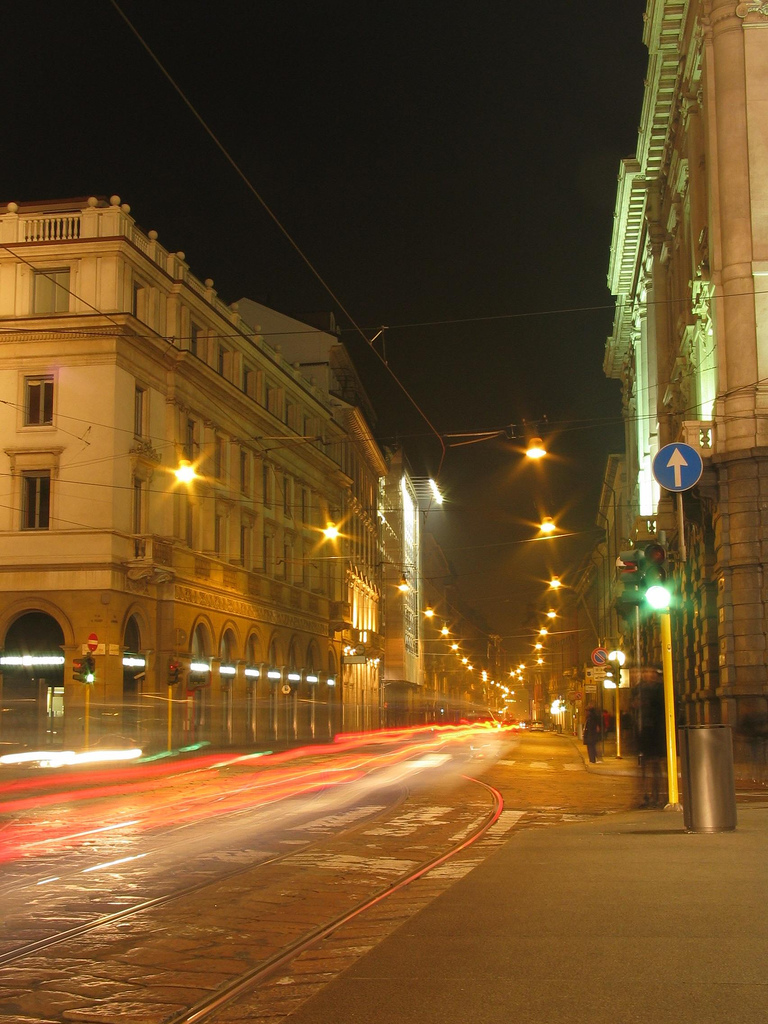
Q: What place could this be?
A: It is a street.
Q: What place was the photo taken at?
A: It was taken at the street.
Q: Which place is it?
A: It is a street.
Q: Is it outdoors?
A: Yes, it is outdoors.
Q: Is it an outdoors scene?
A: Yes, it is outdoors.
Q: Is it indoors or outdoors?
A: It is outdoors.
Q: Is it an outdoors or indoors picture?
A: It is outdoors.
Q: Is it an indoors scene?
A: No, it is outdoors.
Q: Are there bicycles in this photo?
A: No, there are no bicycles.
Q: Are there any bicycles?
A: No, there are no bicycles.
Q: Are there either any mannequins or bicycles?
A: No, there are no bicycles or mannequins.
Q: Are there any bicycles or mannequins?
A: No, there are no bicycles or mannequins.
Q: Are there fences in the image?
A: No, there are no fences.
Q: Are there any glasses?
A: No, there are no glasses.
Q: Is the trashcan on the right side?
A: Yes, the trashcan is on the right of the image.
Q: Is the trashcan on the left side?
A: No, the trashcan is on the right of the image.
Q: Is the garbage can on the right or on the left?
A: The garbage can is on the right of the image.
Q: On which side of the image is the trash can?
A: The trash can is on the right of the image.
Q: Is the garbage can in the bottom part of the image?
A: Yes, the garbage can is in the bottom of the image.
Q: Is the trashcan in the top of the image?
A: No, the trashcan is in the bottom of the image.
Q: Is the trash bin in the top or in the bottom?
A: The trash bin is in the bottom of the image.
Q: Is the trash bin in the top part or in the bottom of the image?
A: The trash bin is in the bottom of the image.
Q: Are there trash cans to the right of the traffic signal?
A: Yes, there is a trash can to the right of the traffic signal.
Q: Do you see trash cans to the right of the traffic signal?
A: Yes, there is a trash can to the right of the traffic signal.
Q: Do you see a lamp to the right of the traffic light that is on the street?
A: No, there is a trash can to the right of the traffic light.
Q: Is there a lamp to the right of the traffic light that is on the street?
A: No, there is a trash can to the right of the traffic light.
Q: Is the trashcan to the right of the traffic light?
A: Yes, the trashcan is to the right of the traffic light.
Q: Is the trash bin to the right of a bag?
A: No, the trash bin is to the right of the traffic light.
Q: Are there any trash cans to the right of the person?
A: Yes, there is a trash can to the right of the person.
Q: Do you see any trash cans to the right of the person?
A: Yes, there is a trash can to the right of the person.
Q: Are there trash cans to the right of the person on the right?
A: Yes, there is a trash can to the right of the person.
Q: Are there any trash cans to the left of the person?
A: No, the trash can is to the right of the person.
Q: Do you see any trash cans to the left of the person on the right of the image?
A: No, the trash can is to the right of the person.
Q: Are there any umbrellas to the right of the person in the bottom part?
A: No, there is a trash can to the right of the person.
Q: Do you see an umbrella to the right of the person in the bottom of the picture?
A: No, there is a trash can to the right of the person.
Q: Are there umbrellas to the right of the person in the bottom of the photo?
A: No, there is a trash can to the right of the person.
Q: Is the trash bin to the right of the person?
A: Yes, the trash bin is to the right of the person.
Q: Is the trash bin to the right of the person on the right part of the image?
A: Yes, the trash bin is to the right of the person.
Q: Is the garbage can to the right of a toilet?
A: No, the garbage can is to the right of the person.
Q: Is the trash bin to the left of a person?
A: No, the trash bin is to the right of a person.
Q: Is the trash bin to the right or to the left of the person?
A: The trash bin is to the right of the person.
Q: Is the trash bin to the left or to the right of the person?
A: The trash bin is to the right of the person.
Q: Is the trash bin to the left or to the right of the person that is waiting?
A: The trash bin is to the right of the person.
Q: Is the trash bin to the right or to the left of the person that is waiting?
A: The trash bin is to the right of the person.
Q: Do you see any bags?
A: No, there are no bags.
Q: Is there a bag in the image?
A: No, there are no bags.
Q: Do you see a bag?
A: No, there are no bags.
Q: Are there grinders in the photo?
A: No, there are no grinders.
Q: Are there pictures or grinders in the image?
A: No, there are no grinders or pictures.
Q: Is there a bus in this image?
A: No, there are no buses.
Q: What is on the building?
A: The sign is on the building.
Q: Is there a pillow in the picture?
A: No, there are no pillows.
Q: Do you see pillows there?
A: No, there are no pillows.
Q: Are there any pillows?
A: No, there are no pillows.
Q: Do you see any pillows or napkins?
A: No, there are no pillows or napkins.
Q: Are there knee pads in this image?
A: No, there are no knee pads.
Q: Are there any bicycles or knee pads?
A: No, there are no knee pads or bicycles.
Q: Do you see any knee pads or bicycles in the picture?
A: No, there are no knee pads or bicycles.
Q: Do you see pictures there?
A: No, there are no pictures.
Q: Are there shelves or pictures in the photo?
A: No, there are no pictures or shelves.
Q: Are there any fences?
A: No, there are no fences.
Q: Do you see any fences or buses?
A: No, there are no fences or buses.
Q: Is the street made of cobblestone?
A: Yes, the street is made of cobblestone.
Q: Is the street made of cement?
A: No, the street is made of cobblestone.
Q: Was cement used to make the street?
A: No, the street is made of cobblestone.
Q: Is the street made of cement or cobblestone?
A: The street is made of cobblestone.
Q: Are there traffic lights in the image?
A: Yes, there is a traffic light.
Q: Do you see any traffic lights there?
A: Yes, there is a traffic light.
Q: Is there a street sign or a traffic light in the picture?
A: Yes, there is a traffic light.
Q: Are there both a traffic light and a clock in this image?
A: No, there is a traffic light but no clocks.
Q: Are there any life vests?
A: No, there are no life vests.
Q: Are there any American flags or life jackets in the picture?
A: No, there are no life jackets or American flags.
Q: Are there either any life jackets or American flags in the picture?
A: No, there are no life jackets or American flags.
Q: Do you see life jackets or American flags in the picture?
A: No, there are no life jackets or American flags.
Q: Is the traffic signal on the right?
A: Yes, the traffic signal is on the right of the image.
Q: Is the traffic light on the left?
A: No, the traffic light is on the right of the image.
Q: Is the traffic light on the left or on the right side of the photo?
A: The traffic light is on the right of the image.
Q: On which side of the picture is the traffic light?
A: The traffic light is on the right of the image.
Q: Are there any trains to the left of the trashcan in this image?
A: No, there is a traffic light to the left of the trashcan.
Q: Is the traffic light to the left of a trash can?
A: Yes, the traffic light is to the left of a trash can.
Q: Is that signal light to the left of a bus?
A: No, the signal light is to the left of a trash can.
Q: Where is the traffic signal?
A: The traffic signal is on the street.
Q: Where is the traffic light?
A: The traffic signal is on the street.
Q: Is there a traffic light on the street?
A: Yes, there is a traffic light on the street.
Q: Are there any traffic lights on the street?
A: Yes, there is a traffic light on the street.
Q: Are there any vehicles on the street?
A: No, there is a traffic light on the street.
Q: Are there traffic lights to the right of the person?
A: Yes, there is a traffic light to the right of the person.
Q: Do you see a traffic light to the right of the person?
A: Yes, there is a traffic light to the right of the person.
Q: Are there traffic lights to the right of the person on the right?
A: Yes, there is a traffic light to the right of the person.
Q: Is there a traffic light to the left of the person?
A: No, the traffic light is to the right of the person.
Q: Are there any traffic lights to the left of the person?
A: No, the traffic light is to the right of the person.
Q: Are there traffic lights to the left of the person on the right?
A: No, the traffic light is to the right of the person.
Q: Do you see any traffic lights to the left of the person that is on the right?
A: No, the traffic light is to the right of the person.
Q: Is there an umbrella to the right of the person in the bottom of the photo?
A: No, there is a traffic light to the right of the person.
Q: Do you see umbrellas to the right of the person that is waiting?
A: No, there is a traffic light to the right of the person.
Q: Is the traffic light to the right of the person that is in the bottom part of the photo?
A: Yes, the traffic light is to the right of the person.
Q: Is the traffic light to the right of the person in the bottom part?
A: Yes, the traffic light is to the right of the person.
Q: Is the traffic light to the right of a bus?
A: No, the traffic light is to the right of the person.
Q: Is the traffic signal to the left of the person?
A: No, the traffic signal is to the right of the person.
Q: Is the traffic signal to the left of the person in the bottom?
A: No, the traffic signal is to the right of the person.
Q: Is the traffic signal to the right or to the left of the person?
A: The traffic signal is to the right of the person.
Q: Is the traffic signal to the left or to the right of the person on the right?
A: The traffic signal is to the right of the person.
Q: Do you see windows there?
A: Yes, there is a window.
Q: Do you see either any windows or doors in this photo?
A: Yes, there is a window.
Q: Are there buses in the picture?
A: No, there are no buses.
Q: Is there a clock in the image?
A: No, there are no clocks.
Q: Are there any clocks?
A: No, there are no clocks.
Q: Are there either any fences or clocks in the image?
A: No, there are no clocks or fences.